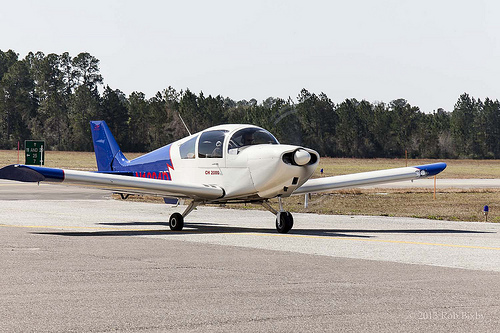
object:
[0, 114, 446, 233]
plane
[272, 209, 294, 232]
wheels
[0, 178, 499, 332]
ground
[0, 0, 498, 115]
sky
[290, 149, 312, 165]
propeller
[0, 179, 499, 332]
asphalt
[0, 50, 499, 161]
trees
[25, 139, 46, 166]
sign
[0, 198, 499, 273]
runway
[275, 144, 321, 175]
nose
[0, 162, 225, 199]
wing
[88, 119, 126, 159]
tail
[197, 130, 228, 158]
window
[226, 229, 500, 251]
line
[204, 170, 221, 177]
writing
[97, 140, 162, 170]
blue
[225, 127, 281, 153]
windshield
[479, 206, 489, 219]
light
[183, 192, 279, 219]
landing gear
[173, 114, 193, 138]
antenna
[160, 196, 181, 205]
engine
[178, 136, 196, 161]
windows